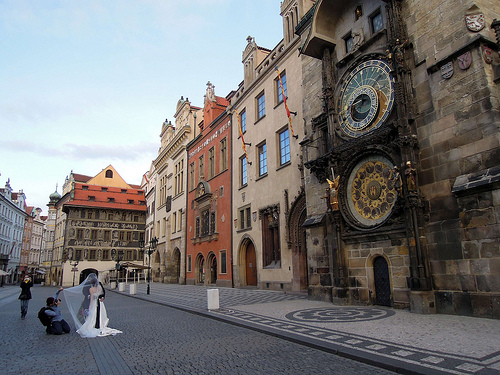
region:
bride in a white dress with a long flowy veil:
[63, 276, 125, 340]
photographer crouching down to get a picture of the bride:
[36, 268, 124, 338]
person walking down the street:
[13, 271, 38, 323]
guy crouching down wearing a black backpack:
[37, 294, 69, 340]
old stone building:
[293, 16, 495, 320]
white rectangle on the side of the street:
[203, 285, 225, 315]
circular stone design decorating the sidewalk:
[277, 282, 399, 353]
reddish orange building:
[181, 108, 232, 289]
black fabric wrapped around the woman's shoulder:
[78, 273, 121, 336]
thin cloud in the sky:
[2, 123, 156, 165]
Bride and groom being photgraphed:
[64, 273, 115, 339]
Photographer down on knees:
[36, 289, 73, 342]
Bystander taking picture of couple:
[13, 269, 34, 329]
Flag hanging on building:
[267, 63, 296, 159]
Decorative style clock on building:
[323, 60, 404, 127]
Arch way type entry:
[353, 242, 401, 305]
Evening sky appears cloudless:
[6, 12, 157, 159]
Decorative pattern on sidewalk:
[275, 297, 412, 345]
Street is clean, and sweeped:
[124, 312, 271, 373]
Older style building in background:
[41, 177, 168, 285]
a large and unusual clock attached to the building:
[339, 59, 393, 135]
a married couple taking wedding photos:
[76, 269, 114, 333]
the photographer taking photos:
[38, 294, 69, 334]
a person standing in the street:
[18, 270, 32, 322]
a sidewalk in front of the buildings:
[111, 276, 498, 373]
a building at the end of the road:
[47, 169, 144, 279]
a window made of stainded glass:
[347, 161, 399, 233]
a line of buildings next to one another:
[143, 35, 323, 285]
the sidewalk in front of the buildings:
[113, 276, 465, 368]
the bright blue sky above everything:
[3, 3, 220, 198]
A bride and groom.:
[61, 270, 122, 340]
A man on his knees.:
[36, 285, 71, 336]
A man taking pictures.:
[36, 287, 73, 337]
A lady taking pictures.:
[18, 273, 35, 323]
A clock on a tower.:
[336, 57, 398, 142]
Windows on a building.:
[236, 69, 292, 192]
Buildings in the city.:
[1, 0, 499, 320]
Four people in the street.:
[16, 271, 124, 339]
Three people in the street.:
[38, 270, 124, 339]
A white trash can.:
[206, 286, 220, 309]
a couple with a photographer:
[34, 263, 134, 350]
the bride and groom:
[56, 257, 128, 347]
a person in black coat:
[11, 269, 37, 326]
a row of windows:
[67, 239, 127, 262]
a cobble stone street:
[123, 306, 264, 368]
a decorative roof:
[40, 177, 75, 220]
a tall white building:
[0, 174, 37, 294]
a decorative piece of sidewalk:
[277, 292, 404, 341]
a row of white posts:
[105, 269, 151, 299]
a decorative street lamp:
[128, 230, 162, 300]